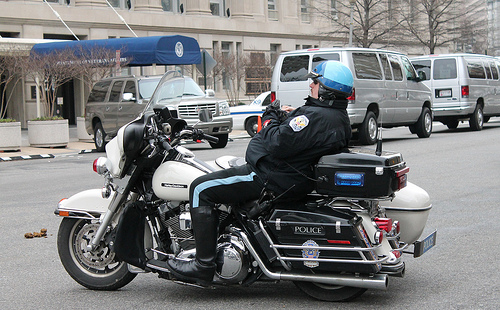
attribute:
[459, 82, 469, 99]
light — red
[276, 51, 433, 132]
van — silver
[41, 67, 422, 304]
motorcycle — white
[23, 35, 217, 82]
awning — blue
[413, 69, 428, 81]
mirror — black 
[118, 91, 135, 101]
mirror — black 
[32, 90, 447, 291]
motorcycle — police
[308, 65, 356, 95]
helmet — blue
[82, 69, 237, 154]
vehicle — silver , parked  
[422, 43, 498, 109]
van — silver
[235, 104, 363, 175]
jacket — black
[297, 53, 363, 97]
helmet — blue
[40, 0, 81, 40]
pole — metal , white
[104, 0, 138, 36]
pole — metal , white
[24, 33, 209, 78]
awning — blue , white